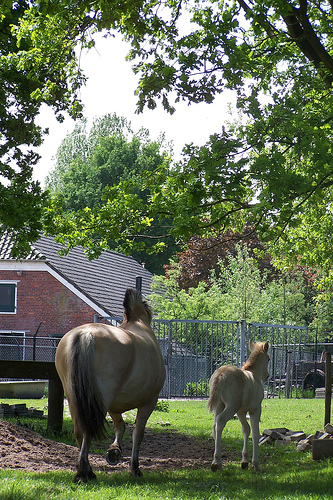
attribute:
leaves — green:
[290, 114, 319, 160]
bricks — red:
[23, 286, 60, 317]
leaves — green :
[143, 64, 184, 100]